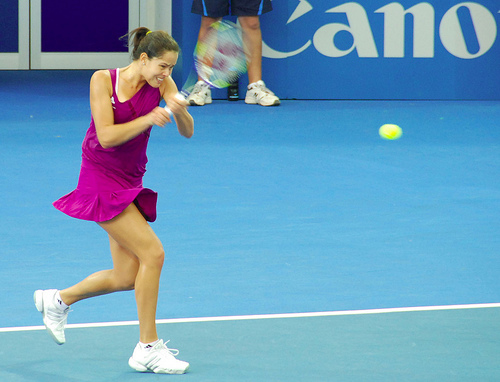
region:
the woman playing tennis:
[28, 25, 193, 371]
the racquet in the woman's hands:
[157, 19, 255, 130]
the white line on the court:
[12, 300, 482, 332]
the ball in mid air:
[378, 122, 402, 139]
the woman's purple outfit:
[53, 65, 165, 227]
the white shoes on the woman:
[29, 283, 189, 375]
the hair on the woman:
[131, 24, 182, 61]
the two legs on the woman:
[24, 182, 189, 371]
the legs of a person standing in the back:
[188, 0, 285, 105]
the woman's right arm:
[86, 69, 171, 151]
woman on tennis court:
[36, 13, 254, 369]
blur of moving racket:
[175, 15, 261, 122]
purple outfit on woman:
[58, 66, 183, 241]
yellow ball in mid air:
[360, 114, 410, 156]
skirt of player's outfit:
[55, 178, 165, 228]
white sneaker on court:
[127, 327, 194, 379]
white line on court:
[273, 298, 374, 331]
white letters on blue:
[310, 1, 485, 71]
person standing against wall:
[182, 3, 283, 110]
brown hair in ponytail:
[129, 20, 159, 47]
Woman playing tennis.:
[30, 23, 212, 374]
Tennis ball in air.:
[367, 115, 422, 148]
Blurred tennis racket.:
[150, 20, 263, 130]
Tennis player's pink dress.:
[49, 67, 168, 228]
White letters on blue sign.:
[259, 0, 494, 65]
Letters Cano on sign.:
[257, 5, 498, 64]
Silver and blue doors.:
[4, 2, 132, 72]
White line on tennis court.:
[192, 297, 490, 324]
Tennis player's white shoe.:
[124, 338, 192, 377]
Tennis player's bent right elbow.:
[81, 97, 138, 151]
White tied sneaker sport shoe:
[16, 287, 74, 344]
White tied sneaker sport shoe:
[118, 333, 187, 371]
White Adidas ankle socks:
[137, 340, 154, 350]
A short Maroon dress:
[62, 62, 162, 234]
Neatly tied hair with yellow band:
[121, 22, 181, 62]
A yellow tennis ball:
[372, 115, 408, 145]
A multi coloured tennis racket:
[155, 27, 257, 114]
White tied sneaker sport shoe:
[245, 80, 285, 111]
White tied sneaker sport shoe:
[191, 78, 210, 103]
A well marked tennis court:
[195, 89, 482, 376]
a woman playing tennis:
[29, 14, 253, 375]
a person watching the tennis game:
[179, 0, 281, 120]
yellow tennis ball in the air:
[370, 113, 408, 151]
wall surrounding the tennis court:
[170, 0, 497, 101]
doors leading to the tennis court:
[1, 0, 177, 90]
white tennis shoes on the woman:
[27, 280, 213, 376]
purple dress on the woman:
[47, 66, 179, 235]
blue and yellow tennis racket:
[150, 12, 257, 136]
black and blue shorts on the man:
[187, 0, 276, 25]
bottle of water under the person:
[220, 68, 241, 108]